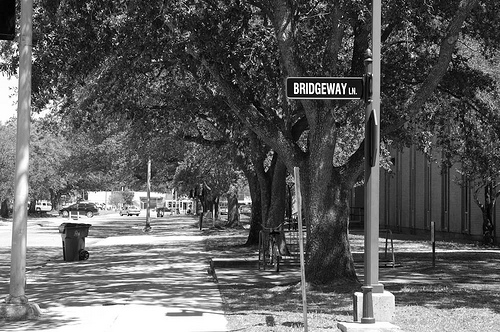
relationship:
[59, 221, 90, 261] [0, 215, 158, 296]
can near curb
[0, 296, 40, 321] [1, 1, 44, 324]
base of light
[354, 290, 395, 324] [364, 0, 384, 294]
block for post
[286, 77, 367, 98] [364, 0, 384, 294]
sign on post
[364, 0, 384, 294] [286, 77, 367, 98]
post for sign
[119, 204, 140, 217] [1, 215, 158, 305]
car on road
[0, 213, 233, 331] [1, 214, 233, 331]
shadows on sidewalk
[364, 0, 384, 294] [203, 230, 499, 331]
post in grass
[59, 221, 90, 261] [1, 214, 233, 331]
can near sidewalk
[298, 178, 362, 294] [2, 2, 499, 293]
trunk of tree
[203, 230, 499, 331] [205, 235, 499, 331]
grass in yard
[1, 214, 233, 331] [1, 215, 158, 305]
sidewalk near street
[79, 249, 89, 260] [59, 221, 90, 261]
wheels of can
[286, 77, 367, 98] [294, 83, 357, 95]
sign has lettering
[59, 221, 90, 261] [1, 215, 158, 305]
can on road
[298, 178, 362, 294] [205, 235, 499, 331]
trunk in yard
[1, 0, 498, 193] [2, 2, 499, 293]
leaves on tree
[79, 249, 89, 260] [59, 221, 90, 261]
wheels on can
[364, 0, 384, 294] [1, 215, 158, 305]
post near road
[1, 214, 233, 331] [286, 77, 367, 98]
sidewalk below sign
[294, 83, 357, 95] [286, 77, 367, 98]
lettering on sign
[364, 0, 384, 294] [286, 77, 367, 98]
post holding sign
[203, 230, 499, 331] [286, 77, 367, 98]
grass below sign